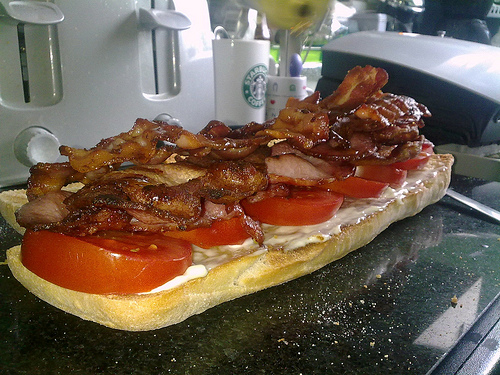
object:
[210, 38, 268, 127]
coffee mug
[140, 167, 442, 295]
mayo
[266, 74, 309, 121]
coffee cup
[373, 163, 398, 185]
ground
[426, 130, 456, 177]
ground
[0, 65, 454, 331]
sandwich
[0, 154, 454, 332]
bread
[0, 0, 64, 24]
lever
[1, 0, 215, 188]
toaster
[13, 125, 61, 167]
knob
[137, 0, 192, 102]
toaster lever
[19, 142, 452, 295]
tomato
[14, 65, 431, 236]
bacon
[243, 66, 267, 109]
logo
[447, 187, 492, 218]
utensil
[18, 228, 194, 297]
tomatoe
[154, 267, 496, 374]
crumbs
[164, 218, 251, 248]
tomato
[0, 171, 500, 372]
counter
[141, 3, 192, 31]
handle